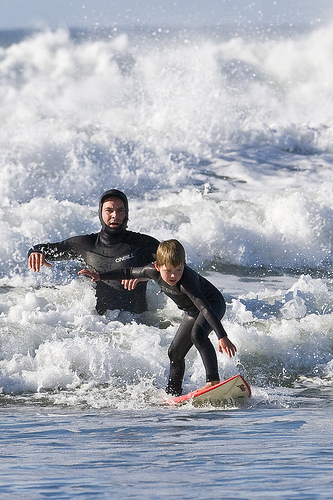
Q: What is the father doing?
A: Watching the son.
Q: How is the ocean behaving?
A: Wildly.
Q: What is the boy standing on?
A: Surfboard.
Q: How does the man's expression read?
A: Overwhelmed.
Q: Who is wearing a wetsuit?
A: A boy.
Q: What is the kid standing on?
A: A board.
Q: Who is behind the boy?
A: A man.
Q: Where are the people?
A: In water.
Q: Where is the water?
A: Around the people.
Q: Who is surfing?
A: The child.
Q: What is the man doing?
A: Standing in water.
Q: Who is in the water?
A: A man and a child.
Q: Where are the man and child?
A: In the water.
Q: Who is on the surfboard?
A: The young boy.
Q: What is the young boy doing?
A: Surfing on the water.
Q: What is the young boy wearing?
A: A wetsuit.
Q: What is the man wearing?
A: A black wet suit.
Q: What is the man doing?
A: Standing in the water.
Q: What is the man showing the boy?
A: He is showing the boy how to surf.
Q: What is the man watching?
A: The man is watching the young boy.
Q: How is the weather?
A: Sunny.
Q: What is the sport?
A: Surfing.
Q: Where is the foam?
A: In the water.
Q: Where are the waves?
A: Behind the surfers.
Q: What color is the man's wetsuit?
A: Black.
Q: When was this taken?
A: During the day.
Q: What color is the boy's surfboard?
A: Red and white.